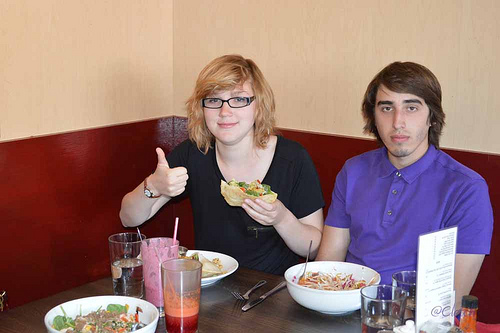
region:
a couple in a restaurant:
[51, 43, 482, 331]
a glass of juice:
[155, 253, 207, 331]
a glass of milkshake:
[136, 235, 168, 310]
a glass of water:
[104, 223, 144, 300]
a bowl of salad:
[281, 248, 386, 321]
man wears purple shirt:
[309, 51, 494, 298]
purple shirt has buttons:
[328, 148, 490, 286]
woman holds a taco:
[106, 41, 331, 271]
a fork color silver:
[226, 267, 266, 304]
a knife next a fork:
[226, 274, 290, 314]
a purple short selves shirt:
[323, 147, 488, 314]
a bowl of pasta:
[283, 258, 379, 318]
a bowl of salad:
[45, 297, 159, 330]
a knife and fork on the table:
[229, 275, 283, 314]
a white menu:
[410, 226, 458, 326]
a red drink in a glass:
[163, 253, 201, 328]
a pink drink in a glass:
[141, 217, 168, 309]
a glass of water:
[108, 228, 142, 296]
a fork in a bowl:
[298, 230, 320, 289]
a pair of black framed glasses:
[206, 86, 251, 116]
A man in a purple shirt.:
[311, 60, 494, 308]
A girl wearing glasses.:
[118, 54, 324, 274]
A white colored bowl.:
[283, 258, 384, 315]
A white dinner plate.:
[185, 245, 240, 290]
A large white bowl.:
[43, 292, 161, 332]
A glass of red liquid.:
[158, 258, 203, 332]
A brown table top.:
[198, 264, 363, 331]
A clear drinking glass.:
[107, 229, 145, 299]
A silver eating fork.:
[228, 276, 268, 301]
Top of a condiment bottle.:
[461, 292, 481, 332]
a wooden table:
[246, 307, 296, 332]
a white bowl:
[314, 287, 332, 307]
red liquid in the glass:
[171, 307, 194, 329]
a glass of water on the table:
[114, 240, 137, 280]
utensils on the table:
[233, 287, 255, 310]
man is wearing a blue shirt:
[408, 195, 445, 220]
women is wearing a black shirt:
[200, 216, 230, 238]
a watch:
[136, 182, 156, 202]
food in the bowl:
[313, 267, 352, 291]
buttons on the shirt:
[388, 172, 401, 179]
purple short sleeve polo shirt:
[333, 151, 484, 279]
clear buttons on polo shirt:
[386, 180, 399, 218]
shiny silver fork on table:
[233, 273, 264, 303]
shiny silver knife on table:
[243, 282, 286, 322]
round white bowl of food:
[285, 255, 376, 319]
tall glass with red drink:
[161, 257, 203, 330]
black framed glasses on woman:
[202, 93, 262, 108]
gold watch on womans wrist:
[141, 175, 157, 203]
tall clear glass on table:
[359, 280, 404, 331]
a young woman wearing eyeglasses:
[191, 87, 256, 114]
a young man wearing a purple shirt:
[346, 147, 468, 281]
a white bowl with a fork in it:
[286, 250, 375, 320]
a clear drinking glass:
[106, 229, 145, 301]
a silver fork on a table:
[231, 279, 265, 299]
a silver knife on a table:
[245, 280, 284, 315]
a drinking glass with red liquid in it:
[158, 257, 198, 331]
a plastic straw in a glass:
[160, 214, 180, 251]